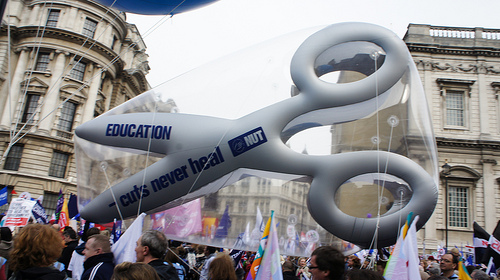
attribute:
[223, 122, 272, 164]
logo — blue, rectangular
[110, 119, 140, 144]
d — blue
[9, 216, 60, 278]
hair — blonde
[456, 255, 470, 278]
flag — blue, yellow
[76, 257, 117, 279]
jacket — black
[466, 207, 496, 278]
flags — black and white with red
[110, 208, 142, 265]
flag — white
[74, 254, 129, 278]
jacket — black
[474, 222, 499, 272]
flags — black, white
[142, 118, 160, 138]
letter 't' — blue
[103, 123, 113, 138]
letter — blue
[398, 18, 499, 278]
building — stone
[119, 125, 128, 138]
letter u — blue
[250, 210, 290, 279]
flag — white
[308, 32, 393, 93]
shape — oval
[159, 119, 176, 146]
letter — blue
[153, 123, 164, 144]
letter o — blue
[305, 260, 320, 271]
shades — dark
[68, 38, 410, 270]
scissors — balloon, midair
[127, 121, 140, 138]
letter c — blue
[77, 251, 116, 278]
jacket — black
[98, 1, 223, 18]
balloon — blue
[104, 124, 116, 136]
letter e — blue